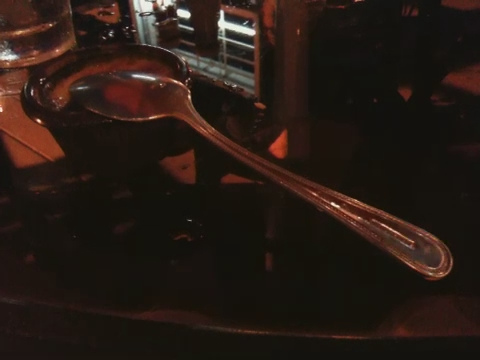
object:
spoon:
[68, 71, 452, 280]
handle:
[193, 124, 452, 280]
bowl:
[22, 44, 191, 169]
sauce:
[63, 65, 122, 70]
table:
[30, 139, 66, 158]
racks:
[217, 11, 253, 76]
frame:
[220, 11, 258, 35]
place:
[0, 3, 479, 360]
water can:
[1, 0, 76, 67]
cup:
[19, 43, 192, 164]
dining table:
[0, 95, 63, 169]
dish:
[35, 86, 59, 116]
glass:
[134, 0, 158, 45]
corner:
[93, 17, 123, 38]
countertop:
[108, 212, 232, 289]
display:
[152, 0, 221, 59]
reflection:
[130, 73, 155, 81]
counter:
[0, 97, 66, 197]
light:
[176, 9, 191, 19]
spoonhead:
[68, 69, 192, 122]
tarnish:
[70, 74, 104, 103]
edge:
[52, 111, 85, 128]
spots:
[114, 72, 131, 78]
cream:
[67, 72, 87, 84]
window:
[134, 0, 257, 87]